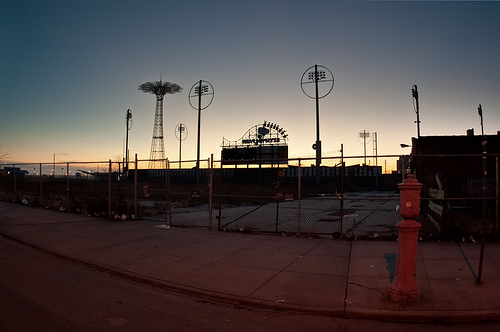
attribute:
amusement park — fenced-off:
[0, 61, 499, 242]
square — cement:
[177, 260, 280, 302]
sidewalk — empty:
[5, 190, 499, 313]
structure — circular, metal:
[293, 55, 337, 165]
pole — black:
[458, 100, 490, 301]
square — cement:
[281, 245, 354, 277]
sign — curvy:
[194, 117, 285, 167]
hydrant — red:
[307, 112, 462, 301]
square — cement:
[423, 271, 498, 318]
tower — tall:
[133, 71, 182, 208]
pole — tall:
[312, 64, 321, 165]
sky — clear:
[34, 10, 461, 56]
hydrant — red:
[387, 159, 441, 312]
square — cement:
[222, 245, 302, 270]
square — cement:
[122, 248, 216, 280]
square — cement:
[353, 234, 422, 257]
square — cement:
[428, 256, 475, 278]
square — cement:
[431, 276, 489, 310]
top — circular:
[135, 74, 182, 102]